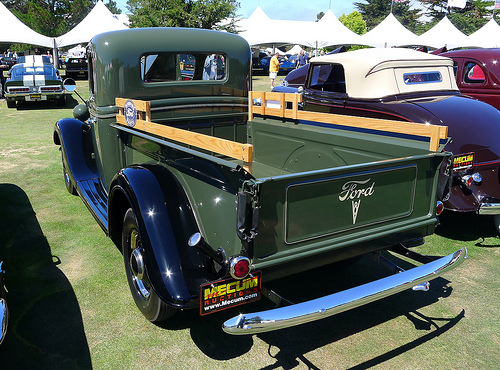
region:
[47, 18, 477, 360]
A green truck is parked on some grass.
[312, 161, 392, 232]
A green truck has the label " Ford " on it.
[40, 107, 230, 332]
Part of a truck is painted blue.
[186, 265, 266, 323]
A truck has a multicolored tag on the back of it.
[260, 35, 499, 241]
A purple and white car is parked.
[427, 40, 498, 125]
A red vehicle is parked.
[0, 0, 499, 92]
Seven tents are in the background.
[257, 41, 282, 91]
A man is standing on some ground.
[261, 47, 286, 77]
A man is wearing a yellow shirt.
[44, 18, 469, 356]
Truck is green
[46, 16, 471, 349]
Truck is old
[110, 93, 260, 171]
Rail of truck on left side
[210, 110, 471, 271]
Truck brand is Ford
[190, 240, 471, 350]
Back bumper is metal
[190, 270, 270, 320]
Plate tag of truck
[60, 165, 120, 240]
Step of drive car is blue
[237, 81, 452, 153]
Wood rail of truck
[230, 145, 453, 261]
Back door of truck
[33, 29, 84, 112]
Mirror of driver site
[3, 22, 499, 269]
Small collection of classic cars.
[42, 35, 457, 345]
Green antique pickup truck.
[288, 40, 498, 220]
Maroon antique coupe.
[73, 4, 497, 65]
White rain shelters.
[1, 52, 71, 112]
Classic american muscle car.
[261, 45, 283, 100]
Man in yellow shirt.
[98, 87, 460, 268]
Metal pickup truck bed with wooden sides.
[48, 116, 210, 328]
Classic american wheel covers.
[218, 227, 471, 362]
Antique chrome rear bumper.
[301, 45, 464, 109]
Canvas top on a classic car.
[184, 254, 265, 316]
"Mecum" license plates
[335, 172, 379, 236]
Ford icon on the green truck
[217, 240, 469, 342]
A shiny chromed rear bumper support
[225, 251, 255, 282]
A round red left taillight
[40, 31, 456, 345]
A green classic truck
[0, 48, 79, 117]
An old stripped muscle car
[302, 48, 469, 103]
A convertible white top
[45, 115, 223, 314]
Black shiny side of the truck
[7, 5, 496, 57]
White-tipped tent coverings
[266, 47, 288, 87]
Man with yellow shirt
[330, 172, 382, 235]
Ford written in white on car